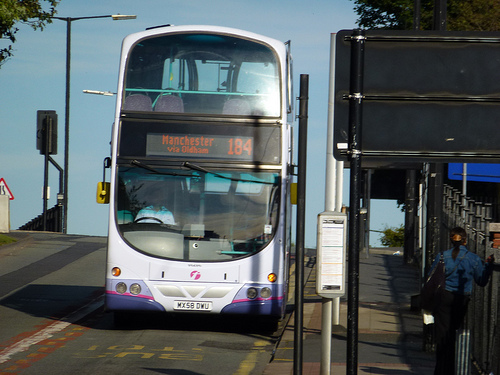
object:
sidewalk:
[267, 235, 487, 374]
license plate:
[173, 298, 215, 309]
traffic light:
[30, 105, 58, 161]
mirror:
[95, 157, 113, 204]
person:
[428, 222, 488, 282]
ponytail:
[448, 235, 460, 260]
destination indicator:
[146, 132, 283, 158]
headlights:
[105, 267, 275, 312]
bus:
[77, 19, 300, 326]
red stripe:
[10, 345, 31, 374]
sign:
[332, 29, 499, 163]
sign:
[0, 176, 10, 200]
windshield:
[115, 160, 280, 259]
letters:
[159, 131, 216, 155]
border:
[0, 175, 15, 201]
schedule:
[315, 212, 348, 296]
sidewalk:
[273, 352, 296, 373]